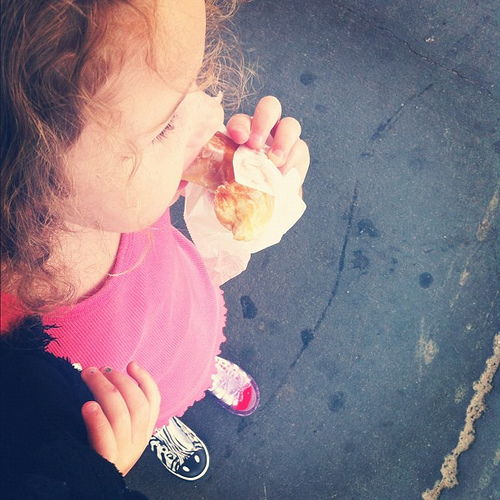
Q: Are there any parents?
A: No, there are no parents.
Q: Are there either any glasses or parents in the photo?
A: No, there are no parents or glasses.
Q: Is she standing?
A: Yes, the girl is standing.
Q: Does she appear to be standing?
A: Yes, the girl is standing.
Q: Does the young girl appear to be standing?
A: Yes, the girl is standing.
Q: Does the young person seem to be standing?
A: Yes, the girl is standing.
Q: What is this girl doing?
A: The girl is standing.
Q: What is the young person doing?
A: The girl is standing.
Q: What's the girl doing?
A: The girl is standing.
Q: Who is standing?
A: The girl is standing.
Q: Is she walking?
A: No, the girl is standing.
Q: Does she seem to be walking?
A: No, the girl is standing.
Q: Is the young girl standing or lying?
A: The girl is standing.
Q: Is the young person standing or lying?
A: The girl is standing.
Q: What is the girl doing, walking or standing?
A: The girl is standing.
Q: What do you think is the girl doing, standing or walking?
A: The girl is standing.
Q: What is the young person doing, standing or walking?
A: The girl is standing.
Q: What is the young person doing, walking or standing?
A: The girl is standing.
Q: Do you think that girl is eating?
A: Yes, the girl is eating.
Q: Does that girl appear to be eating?
A: Yes, the girl is eating.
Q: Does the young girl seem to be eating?
A: Yes, the girl is eating.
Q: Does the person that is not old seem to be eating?
A: Yes, the girl is eating.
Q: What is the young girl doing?
A: The girl is eating.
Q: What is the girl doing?
A: The girl is eating.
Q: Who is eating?
A: The girl is eating.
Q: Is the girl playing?
A: No, the girl is eating.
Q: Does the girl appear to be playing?
A: No, the girl is eating.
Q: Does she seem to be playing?
A: No, the girl is eating.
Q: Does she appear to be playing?
A: No, the girl is eating.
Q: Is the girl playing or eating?
A: The girl is eating.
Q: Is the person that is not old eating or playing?
A: The girl is eating.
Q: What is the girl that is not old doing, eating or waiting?
A: The girl is eating.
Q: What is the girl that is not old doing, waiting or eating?
A: The girl is eating.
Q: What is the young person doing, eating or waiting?
A: The girl is eating.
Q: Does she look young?
A: Yes, the girl is young.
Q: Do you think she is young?
A: Yes, the girl is young.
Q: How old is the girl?
A: The girl is young.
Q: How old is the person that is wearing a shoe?
A: The girl is young.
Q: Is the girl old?
A: No, the girl is young.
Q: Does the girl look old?
A: No, the girl is young.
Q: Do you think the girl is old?
A: No, the girl is young.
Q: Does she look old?
A: No, the girl is young.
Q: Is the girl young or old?
A: The girl is young.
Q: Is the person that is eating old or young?
A: The girl is young.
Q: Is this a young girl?
A: Yes, this is a young girl.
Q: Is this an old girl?
A: No, this is a young girl.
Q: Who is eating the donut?
A: The girl is eating the donut.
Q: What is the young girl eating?
A: The girl is eating a donut.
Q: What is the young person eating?
A: The girl is eating a donut.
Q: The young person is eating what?
A: The girl is eating a donut.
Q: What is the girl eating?
A: The girl is eating a donut.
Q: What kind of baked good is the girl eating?
A: The girl is eating a doughnut.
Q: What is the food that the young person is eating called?
A: The food is a donut.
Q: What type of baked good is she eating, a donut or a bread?
A: The girl is eating a donut.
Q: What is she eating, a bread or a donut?
A: The girl is eating a donut.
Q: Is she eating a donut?
A: Yes, the girl is eating a donut.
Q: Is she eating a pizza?
A: No, the girl is eating a donut.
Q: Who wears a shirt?
A: The girl wears a shirt.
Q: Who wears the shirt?
A: The girl wears a shirt.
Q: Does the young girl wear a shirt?
A: Yes, the girl wears a shirt.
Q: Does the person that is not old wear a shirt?
A: Yes, the girl wears a shirt.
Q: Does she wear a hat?
A: No, the girl wears a shirt.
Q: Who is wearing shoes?
A: The girl is wearing shoes.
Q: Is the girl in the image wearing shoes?
A: Yes, the girl is wearing shoes.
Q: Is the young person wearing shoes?
A: Yes, the girl is wearing shoes.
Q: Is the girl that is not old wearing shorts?
A: No, the girl is wearing shoes.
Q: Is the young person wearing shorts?
A: No, the girl is wearing shoes.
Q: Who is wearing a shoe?
A: The girl is wearing a shoe.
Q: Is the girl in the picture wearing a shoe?
A: Yes, the girl is wearing a shoe.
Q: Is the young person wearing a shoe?
A: Yes, the girl is wearing a shoe.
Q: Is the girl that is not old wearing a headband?
A: No, the girl is wearing a shoe.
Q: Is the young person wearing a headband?
A: No, the girl is wearing a shoe.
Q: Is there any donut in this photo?
A: Yes, there is a donut.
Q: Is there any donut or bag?
A: Yes, there is a donut.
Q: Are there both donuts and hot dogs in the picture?
A: No, there is a donut but no hot dogs.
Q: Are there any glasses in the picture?
A: No, there are no glasses.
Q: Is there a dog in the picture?
A: No, there are no dogs.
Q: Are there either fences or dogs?
A: No, there are no dogs or fences.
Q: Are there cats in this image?
A: No, there are no cats.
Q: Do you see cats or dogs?
A: No, there are no cats or dogs.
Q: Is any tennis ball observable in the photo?
A: No, there are no tennis balls.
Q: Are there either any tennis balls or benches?
A: No, there are no tennis balls or benches.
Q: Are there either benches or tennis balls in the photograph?
A: No, there are no tennis balls or benches.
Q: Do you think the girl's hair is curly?
A: Yes, the hair is curly.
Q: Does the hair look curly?
A: Yes, the hair is curly.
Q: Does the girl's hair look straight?
A: No, the hair is curly.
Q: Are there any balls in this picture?
A: No, there are no balls.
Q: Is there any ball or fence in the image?
A: No, there are no balls or fences.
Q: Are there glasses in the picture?
A: No, there are no glasses.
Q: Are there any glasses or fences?
A: No, there are no glasses or fences.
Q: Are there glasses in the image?
A: No, there are no glasses.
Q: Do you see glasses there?
A: No, there are no glasses.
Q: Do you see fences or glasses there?
A: No, there are no glasses or fences.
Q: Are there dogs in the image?
A: No, there are no dogs.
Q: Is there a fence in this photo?
A: No, there are no fences.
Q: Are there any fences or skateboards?
A: No, there are no fences or skateboards.